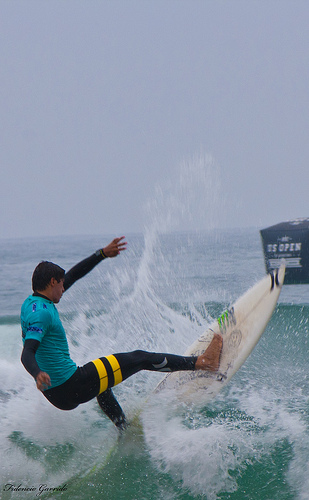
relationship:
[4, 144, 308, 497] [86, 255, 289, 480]
foam near surfboard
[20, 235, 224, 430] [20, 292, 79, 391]
man wearing shirt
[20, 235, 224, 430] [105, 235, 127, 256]
man lifting h hand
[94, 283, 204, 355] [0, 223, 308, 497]
waves of water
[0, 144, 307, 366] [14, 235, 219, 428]
water splashed up in front of man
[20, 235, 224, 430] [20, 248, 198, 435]
man on swim suit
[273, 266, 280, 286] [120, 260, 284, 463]
stripes on surfboard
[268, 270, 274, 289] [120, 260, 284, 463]
stripes on surfboard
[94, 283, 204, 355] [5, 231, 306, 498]
waves crashing ocean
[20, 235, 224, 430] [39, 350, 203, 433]
man wearing pants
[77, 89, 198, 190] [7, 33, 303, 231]
clouds in sky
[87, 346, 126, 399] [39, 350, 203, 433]
stripes on pants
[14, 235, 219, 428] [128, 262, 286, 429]
man on board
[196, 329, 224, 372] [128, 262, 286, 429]
foot on board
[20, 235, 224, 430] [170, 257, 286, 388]
man on board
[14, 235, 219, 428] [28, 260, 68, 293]
man with hair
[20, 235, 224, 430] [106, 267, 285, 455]
man on surfboard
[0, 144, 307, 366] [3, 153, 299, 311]
water spraying in air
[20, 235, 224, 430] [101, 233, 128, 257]
man with hand